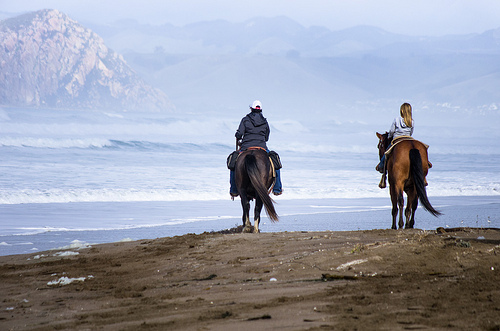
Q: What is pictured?
A: Two horses.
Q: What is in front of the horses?
A: Waves cresting.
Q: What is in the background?
A: Mountains.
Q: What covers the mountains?
A: Misty clouds.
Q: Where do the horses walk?
A: On sand.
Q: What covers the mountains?
A: Fog.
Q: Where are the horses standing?
A: On brown dirt.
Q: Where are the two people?
A: On the horses.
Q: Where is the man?
A: On the black horse.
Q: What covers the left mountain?
A: Snow.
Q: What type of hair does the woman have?
A: Long blonde hair.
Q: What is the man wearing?
A: Dark blue jack and white hat.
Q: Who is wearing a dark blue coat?
A: Gentleman on the horse.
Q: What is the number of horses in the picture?
A: Two.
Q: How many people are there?
A: Two.